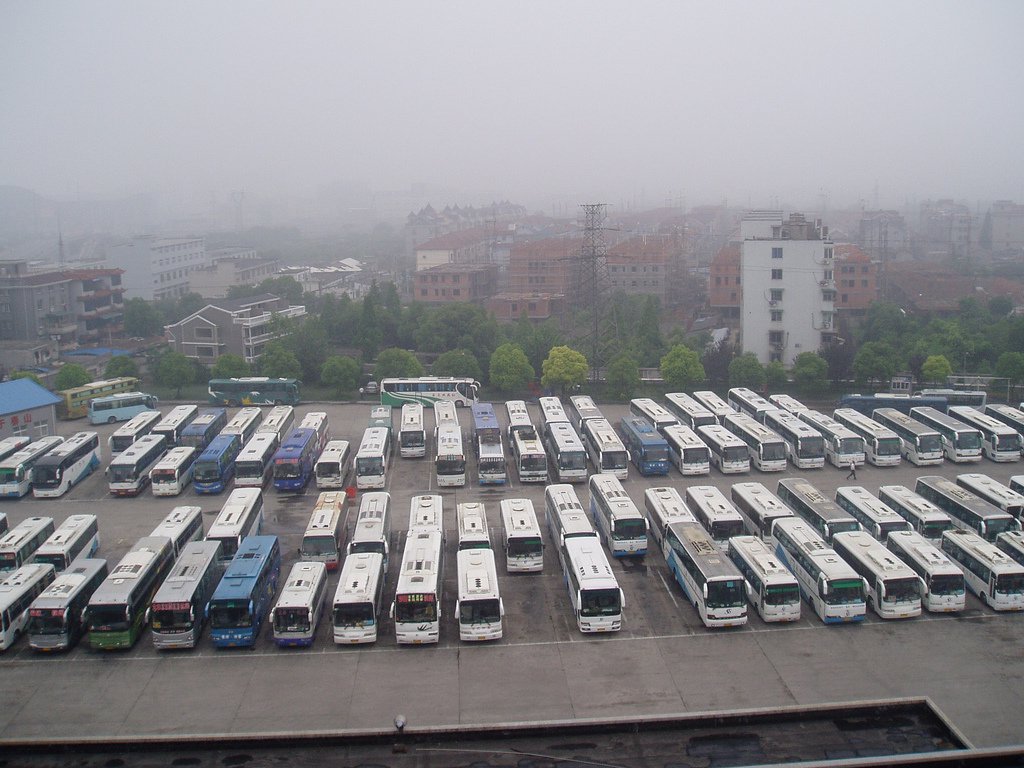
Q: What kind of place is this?
A: It is a parking lot.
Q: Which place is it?
A: It is a parking lot.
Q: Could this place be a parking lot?
A: Yes, it is a parking lot.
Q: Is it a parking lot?
A: Yes, it is a parking lot.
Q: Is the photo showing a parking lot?
A: Yes, it is showing a parking lot.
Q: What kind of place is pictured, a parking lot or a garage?
A: It is a parking lot.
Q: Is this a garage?
A: No, it is a parking lot.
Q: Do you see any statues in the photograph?
A: No, there are no statues.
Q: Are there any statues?
A: No, there are no statues.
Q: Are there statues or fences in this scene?
A: No, there are no statues or fences.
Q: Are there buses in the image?
A: Yes, there are buses.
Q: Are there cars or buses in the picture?
A: Yes, there are buses.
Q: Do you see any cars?
A: No, there are no cars.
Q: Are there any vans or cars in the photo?
A: No, there are no cars or vans.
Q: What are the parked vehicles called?
A: The vehicles are buses.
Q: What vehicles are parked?
A: The vehicles are buses.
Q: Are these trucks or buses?
A: These are buses.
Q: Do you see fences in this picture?
A: No, there are no fences.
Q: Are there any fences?
A: No, there are no fences.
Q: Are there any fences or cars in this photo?
A: No, there are no fences or cars.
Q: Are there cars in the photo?
A: No, there are no cars.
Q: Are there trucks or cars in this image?
A: No, there are no cars or trucks.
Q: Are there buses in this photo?
A: Yes, there is a bus.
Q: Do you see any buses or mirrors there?
A: Yes, there is a bus.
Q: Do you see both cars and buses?
A: No, there is a bus but no cars.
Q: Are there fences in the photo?
A: No, there are no fences.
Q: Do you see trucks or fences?
A: No, there are no fences or trucks.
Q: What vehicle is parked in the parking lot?
A: The vehicle is a bus.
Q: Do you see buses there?
A: Yes, there is a bus.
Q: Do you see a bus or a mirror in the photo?
A: Yes, there is a bus.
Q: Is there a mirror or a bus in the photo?
A: Yes, there is a bus.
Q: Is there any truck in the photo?
A: No, there are no trucks.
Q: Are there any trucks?
A: No, there are no trucks.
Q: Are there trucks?
A: No, there are no trucks.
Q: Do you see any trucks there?
A: No, there are no trucks.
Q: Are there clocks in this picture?
A: No, there are no clocks.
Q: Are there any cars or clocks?
A: No, there are no clocks or cars.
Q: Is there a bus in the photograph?
A: Yes, there is a bus.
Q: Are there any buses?
A: Yes, there is a bus.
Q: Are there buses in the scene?
A: Yes, there is a bus.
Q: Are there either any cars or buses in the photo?
A: Yes, there is a bus.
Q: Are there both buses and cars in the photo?
A: No, there is a bus but no cars.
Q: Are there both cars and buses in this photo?
A: No, there is a bus but no cars.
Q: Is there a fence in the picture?
A: No, there are no fences.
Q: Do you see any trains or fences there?
A: No, there are no fences or trains.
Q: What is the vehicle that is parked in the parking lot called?
A: The vehicle is a bus.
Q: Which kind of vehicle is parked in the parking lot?
A: The vehicle is a bus.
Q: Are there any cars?
A: No, there are no cars.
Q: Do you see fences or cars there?
A: No, there are no cars or fences.